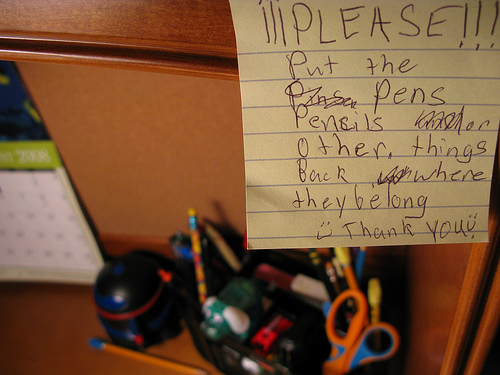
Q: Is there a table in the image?
A: Yes, there is a table.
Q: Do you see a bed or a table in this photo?
A: Yes, there is a table.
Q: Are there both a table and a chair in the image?
A: No, there is a table but no chairs.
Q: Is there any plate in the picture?
A: No, there are no plates.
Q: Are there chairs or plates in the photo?
A: No, there are no plates or chairs.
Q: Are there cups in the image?
A: No, there are no cups.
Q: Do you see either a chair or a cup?
A: No, there are no cups or chairs.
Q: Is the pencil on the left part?
A: Yes, the pencil is on the left of the image.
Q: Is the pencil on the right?
A: No, the pencil is on the left of the image.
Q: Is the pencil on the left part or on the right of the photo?
A: The pencil is on the left of the image.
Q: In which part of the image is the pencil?
A: The pencil is on the left of the image.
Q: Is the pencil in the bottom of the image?
A: Yes, the pencil is in the bottom of the image.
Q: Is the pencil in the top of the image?
A: No, the pencil is in the bottom of the image.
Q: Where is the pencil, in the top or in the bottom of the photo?
A: The pencil is in the bottom of the image.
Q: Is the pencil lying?
A: Yes, the pencil is lying.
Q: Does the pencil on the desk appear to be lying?
A: Yes, the pencil is lying.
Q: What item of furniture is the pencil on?
A: The pencil is on the desk.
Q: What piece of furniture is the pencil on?
A: The pencil is on the desk.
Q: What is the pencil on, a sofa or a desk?
A: The pencil is on a desk.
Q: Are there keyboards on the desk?
A: No, there is a pencil on the desk.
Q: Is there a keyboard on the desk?
A: No, there is a pencil on the desk.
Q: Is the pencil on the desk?
A: Yes, the pencil is on the desk.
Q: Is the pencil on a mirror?
A: No, the pencil is on the desk.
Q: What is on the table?
A: The pencil is on the table.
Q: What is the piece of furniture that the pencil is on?
A: The piece of furniture is a table.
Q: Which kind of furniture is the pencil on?
A: The pencil is on the table.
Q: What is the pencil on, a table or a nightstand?
A: The pencil is on a table.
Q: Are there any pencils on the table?
A: Yes, there is a pencil on the table.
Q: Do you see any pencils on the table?
A: Yes, there is a pencil on the table.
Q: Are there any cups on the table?
A: No, there is a pencil on the table.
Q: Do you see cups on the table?
A: No, there is a pencil on the table.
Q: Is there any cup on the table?
A: No, there is a pencil on the table.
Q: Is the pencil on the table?
A: Yes, the pencil is on the table.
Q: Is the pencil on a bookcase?
A: No, the pencil is on the table.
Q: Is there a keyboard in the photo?
A: No, there are no keyboards.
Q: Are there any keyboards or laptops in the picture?
A: No, there are no keyboards or laptops.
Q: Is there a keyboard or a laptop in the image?
A: No, there are no keyboards or laptops.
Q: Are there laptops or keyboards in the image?
A: No, there are no keyboards or laptops.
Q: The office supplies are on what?
A: The office supplies are on the desk.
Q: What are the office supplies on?
A: The office supplies are on the desk.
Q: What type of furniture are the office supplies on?
A: The office supplies are on the desk.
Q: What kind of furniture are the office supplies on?
A: The office supplies are on the desk.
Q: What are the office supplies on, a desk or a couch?
A: The office supplies are on a desk.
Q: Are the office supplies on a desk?
A: Yes, the office supplies are on a desk.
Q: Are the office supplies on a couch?
A: No, the office supplies are on a desk.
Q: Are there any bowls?
A: No, there are no bowls.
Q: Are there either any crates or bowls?
A: No, there are no bowls or crates.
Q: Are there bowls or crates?
A: No, there are no bowls or crates.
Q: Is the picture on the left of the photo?
A: Yes, the picture is on the left of the image.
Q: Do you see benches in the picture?
A: No, there are no benches.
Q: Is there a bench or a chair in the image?
A: No, there are no benches or chairs.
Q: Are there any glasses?
A: No, there are no glasses.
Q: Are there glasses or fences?
A: No, there are no glasses or fences.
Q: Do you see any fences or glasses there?
A: No, there are no glasses or fences.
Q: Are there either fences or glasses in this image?
A: No, there are no glasses or fences.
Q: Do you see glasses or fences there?
A: No, there are no glasses or fences.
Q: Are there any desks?
A: Yes, there is a desk.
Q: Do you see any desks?
A: Yes, there is a desk.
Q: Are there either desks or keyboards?
A: Yes, there is a desk.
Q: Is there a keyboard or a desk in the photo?
A: Yes, there is a desk.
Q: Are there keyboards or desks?
A: Yes, there is a desk.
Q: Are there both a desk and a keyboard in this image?
A: No, there is a desk but no keyboards.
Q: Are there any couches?
A: No, there are no couches.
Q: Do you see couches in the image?
A: No, there are no couches.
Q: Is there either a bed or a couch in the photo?
A: No, there are no couches or beds.